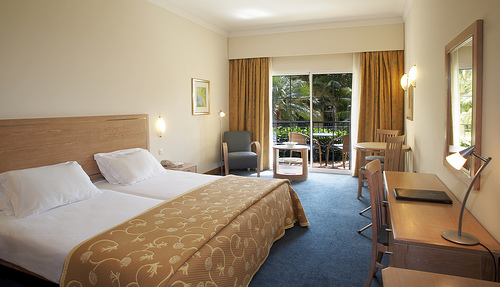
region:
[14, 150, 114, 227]
a pillow on a bed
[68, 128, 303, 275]
a blanket on a bed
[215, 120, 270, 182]
a chair in a room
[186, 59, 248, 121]
a picture on a wall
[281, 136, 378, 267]
blue carpet on the floor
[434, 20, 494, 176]
a mirror on th wall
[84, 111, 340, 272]
a brown blanket on a bed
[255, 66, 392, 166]
a window in a room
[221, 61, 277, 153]
curtains on the window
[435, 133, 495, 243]
a light on a table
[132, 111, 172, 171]
a lamp beside a bed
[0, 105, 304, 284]
a king bed in a bedroom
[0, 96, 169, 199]
brown headboard of bed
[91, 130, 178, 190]
white pillow on the bed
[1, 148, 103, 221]
white pillow on the bed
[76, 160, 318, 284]
brown comforter on a bed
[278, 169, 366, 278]
carpet of room is blue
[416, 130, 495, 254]
a lamp on desk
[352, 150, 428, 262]
a chair in front desk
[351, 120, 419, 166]
two chairs in front a table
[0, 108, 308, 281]
A bed in the foreground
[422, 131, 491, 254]
A small lamp in the foreground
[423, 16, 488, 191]
A mirror on the wall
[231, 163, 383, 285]
The carpet is blue in color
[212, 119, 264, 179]
A gray color chair in the background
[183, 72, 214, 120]
A picture frame on the wall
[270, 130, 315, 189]
A small table in the background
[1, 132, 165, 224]
White pillows on the bed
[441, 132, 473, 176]
Lamp light is on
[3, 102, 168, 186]
Headboard is made of wood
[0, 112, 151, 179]
light colored wooden head board on bed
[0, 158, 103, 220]
a fluffy white pillow on the bed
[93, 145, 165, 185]
a fluffy white pillow on the bed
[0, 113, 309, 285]
a king size bed in motel room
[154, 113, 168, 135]
a light fixture on the wall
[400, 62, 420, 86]
a light fixture on the wall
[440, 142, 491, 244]
a silver lamp on the dresser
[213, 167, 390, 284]
blue carpeting on the floor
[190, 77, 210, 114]
a framed picture on the wall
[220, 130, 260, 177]
a grey chair with wooden arms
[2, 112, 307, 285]
king size bed in motel room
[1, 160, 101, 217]
a white fluffy pillow on the bed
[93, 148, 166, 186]
a white fluffy pillow on the bed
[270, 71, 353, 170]
sliding glass doors in motel room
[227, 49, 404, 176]
gold drapes in motel room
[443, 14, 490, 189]
a mirror on the wall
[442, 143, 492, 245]
a lamp on top of dresser